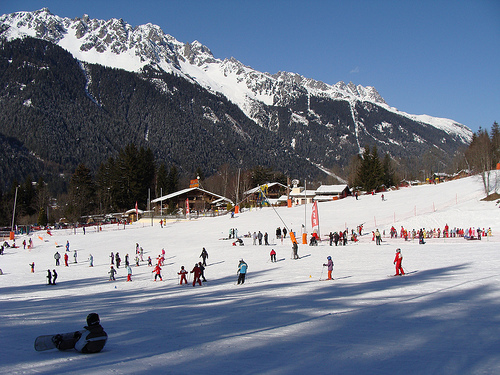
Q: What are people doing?
A: Skiing.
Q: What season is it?
A: Winter.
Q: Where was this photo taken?
A: Ski resort.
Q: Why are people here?
A: To have fun.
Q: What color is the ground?
A: White.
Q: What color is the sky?
A: Blue.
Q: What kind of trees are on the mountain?
A: Evergreens.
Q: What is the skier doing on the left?
A: Sitting down.